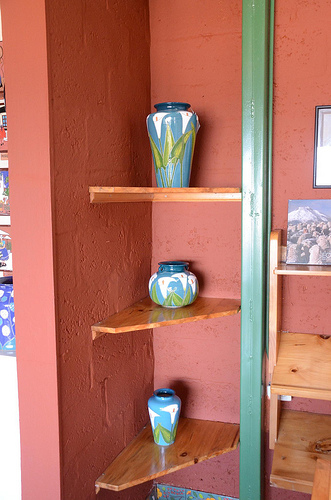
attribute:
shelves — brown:
[52, 101, 299, 479]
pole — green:
[237, 0, 276, 498]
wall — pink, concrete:
[0, 0, 329, 498]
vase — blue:
[144, 100, 203, 187]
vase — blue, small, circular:
[145, 257, 198, 307]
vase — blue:
[146, 381, 180, 446]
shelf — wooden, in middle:
[88, 289, 243, 335]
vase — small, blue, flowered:
[142, 384, 185, 447]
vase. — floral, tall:
[123, 83, 224, 210]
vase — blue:
[130, 83, 212, 190]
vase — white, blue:
[149, 260, 199, 307]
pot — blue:
[146, 259, 200, 310]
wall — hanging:
[48, 3, 326, 491]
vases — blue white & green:
[146, 100, 201, 188]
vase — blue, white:
[145, 101, 197, 186]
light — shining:
[311, 141, 329, 186]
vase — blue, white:
[148, 388, 181, 445]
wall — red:
[51, 18, 99, 132]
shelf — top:
[88, 187, 242, 203]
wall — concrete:
[3, 0, 153, 497]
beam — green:
[238, 0, 276, 498]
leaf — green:
[168, 129, 192, 163]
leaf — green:
[163, 121, 175, 169]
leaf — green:
[146, 132, 167, 173]